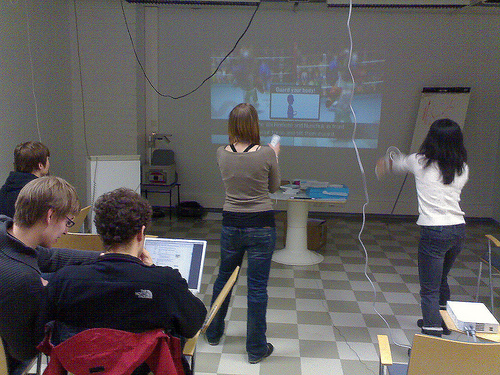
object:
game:
[447, 296, 497, 331]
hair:
[227, 102, 262, 142]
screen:
[143, 240, 198, 289]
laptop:
[142, 226, 211, 287]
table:
[260, 176, 354, 272]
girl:
[203, 99, 317, 368]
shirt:
[225, 147, 281, 223]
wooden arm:
[377, 334, 390, 373]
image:
[188, 0, 399, 125]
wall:
[97, 7, 199, 122]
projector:
[444, 301, 500, 334]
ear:
[137, 224, 147, 240]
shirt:
[412, 150, 469, 224]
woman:
[204, 92, 282, 367]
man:
[39, 189, 206, 334]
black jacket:
[60, 244, 212, 357]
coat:
[34, 330, 189, 374]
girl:
[378, 109, 492, 274]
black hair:
[417, 115, 470, 185]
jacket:
[57, 255, 192, 350]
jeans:
[418, 222, 466, 337]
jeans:
[211, 213, 276, 364]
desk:
[369, 327, 499, 369]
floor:
[277, 247, 403, 368]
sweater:
[224, 145, 284, 202]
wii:
[444, 299, 498, 338]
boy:
[69, 189, 188, 372]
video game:
[210, 45, 382, 148]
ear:
[38, 203, 63, 228]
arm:
[375, 329, 393, 367]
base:
[275, 192, 317, 263]